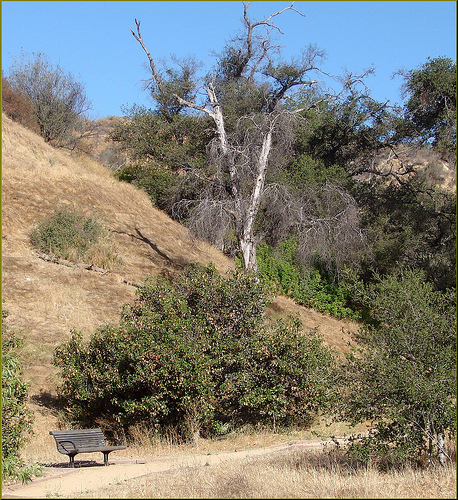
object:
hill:
[21, 132, 160, 234]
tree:
[161, 74, 340, 283]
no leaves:
[171, 200, 186, 224]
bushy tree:
[43, 261, 336, 439]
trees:
[60, 260, 329, 435]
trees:
[325, 265, 455, 495]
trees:
[123, 3, 455, 341]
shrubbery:
[244, 235, 384, 335]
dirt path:
[4, 423, 403, 498]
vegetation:
[105, 455, 452, 499]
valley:
[71, 115, 149, 214]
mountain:
[19, 55, 388, 409]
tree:
[341, 158, 431, 210]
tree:
[7, 42, 105, 157]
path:
[168, 428, 375, 456]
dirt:
[72, 470, 103, 485]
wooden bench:
[48, 426, 127, 464]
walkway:
[5, 454, 209, 486]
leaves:
[268, 156, 343, 201]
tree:
[263, 103, 375, 324]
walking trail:
[28, 392, 389, 493]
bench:
[47, 426, 126, 469]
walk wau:
[41, 421, 427, 492]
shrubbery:
[52, 263, 345, 440]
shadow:
[110, 222, 181, 269]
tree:
[175, 42, 278, 303]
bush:
[103, 172, 297, 493]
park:
[90, 85, 448, 405]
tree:
[30, 204, 126, 274]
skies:
[6, 8, 451, 122]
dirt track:
[181, 431, 323, 478]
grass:
[297, 458, 454, 498]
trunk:
[224, 231, 278, 293]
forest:
[109, 61, 448, 441]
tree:
[91, 284, 341, 431]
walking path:
[16, 427, 380, 498]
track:
[17, 424, 368, 497]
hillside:
[4, 102, 380, 455]